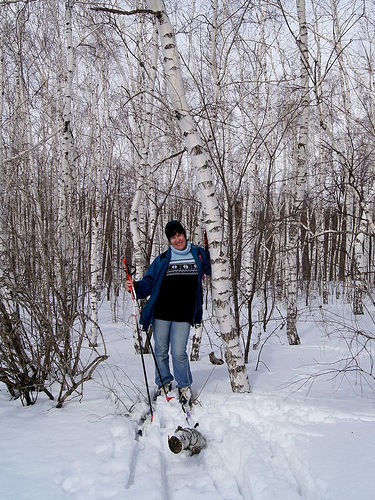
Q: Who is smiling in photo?
A: A woman.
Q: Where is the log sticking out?
A: Of snow.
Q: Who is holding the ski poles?
A: The woman.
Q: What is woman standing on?
A: Snow.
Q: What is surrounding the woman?
A: Trees.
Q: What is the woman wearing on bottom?
A: Jeans.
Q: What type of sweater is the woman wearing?
A: Turtleneck.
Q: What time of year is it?
A: Winter.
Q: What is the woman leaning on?
A: Tree.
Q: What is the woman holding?
A: Ski pole.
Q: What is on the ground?
A: Snow.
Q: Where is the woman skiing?
A: Woods.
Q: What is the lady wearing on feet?
A: Skis.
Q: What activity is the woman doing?
A: Skiing.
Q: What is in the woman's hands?
A: Ski poles.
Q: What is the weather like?
A: Cold.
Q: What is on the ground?
A: Snow.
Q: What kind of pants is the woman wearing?
A: Jeans.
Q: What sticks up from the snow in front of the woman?
A: Stump.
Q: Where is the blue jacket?
A: On the woman.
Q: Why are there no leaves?
A: It's winter.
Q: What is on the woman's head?
A: Cap.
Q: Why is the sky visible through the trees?
A: There are no leaves.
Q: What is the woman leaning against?
A: A tree.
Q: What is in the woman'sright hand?
A: Ski poles.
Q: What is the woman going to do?
A: Ski.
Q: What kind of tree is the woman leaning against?
A: White birch.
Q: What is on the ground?
A: Snow.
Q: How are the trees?
A: Bare.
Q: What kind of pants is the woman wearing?
A: Blue jeans.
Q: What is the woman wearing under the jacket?
A: A sweater.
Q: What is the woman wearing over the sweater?
A: A blue jacket.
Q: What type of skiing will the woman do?
A: Cross country.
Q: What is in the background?
A: Trees without leaves.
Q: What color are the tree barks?
A: White.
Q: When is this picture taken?
A: Daytime.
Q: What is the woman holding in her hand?
A: Ski poles.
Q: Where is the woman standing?
A: Between the trees.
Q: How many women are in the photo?
A: One.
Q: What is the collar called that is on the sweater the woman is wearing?
A: A turtleneck.